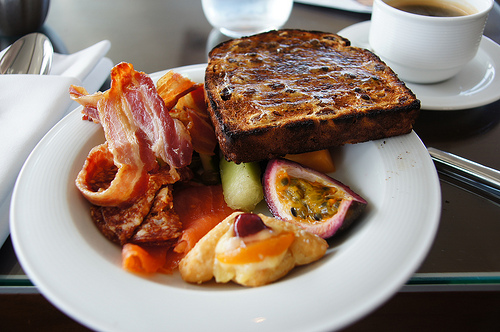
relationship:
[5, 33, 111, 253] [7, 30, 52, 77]
napkin around silverware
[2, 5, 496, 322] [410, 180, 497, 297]
table made of glass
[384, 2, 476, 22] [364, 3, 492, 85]
coffee in a cup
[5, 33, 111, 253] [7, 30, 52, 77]
napkin has a spoon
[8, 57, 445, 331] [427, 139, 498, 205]
plate by a knife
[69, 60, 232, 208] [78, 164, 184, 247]
bacon on top of salami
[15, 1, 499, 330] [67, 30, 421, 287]
plate has food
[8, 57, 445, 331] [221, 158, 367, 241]
bowl has fruit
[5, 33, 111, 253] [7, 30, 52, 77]
napkin wrapped around a spoon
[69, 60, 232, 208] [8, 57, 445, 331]
bacon on plate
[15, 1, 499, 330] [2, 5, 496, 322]
breakfast on table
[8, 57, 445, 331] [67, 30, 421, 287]
plate has food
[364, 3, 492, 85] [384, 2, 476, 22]
cup has coffee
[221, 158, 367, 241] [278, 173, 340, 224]
fruit has seeds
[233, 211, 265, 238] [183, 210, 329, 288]
cherry on a crepe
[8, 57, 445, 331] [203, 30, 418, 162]
plate has a topping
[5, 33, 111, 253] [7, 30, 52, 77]
napkin with a spoon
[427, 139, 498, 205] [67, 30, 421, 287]
utensil for eating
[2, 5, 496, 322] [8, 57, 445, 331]
table has a plate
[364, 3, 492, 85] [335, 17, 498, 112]
mug on a plate